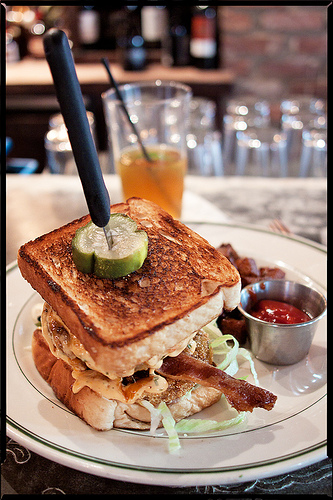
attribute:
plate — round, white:
[6, 217, 327, 487]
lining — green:
[3, 219, 332, 476]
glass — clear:
[101, 80, 193, 223]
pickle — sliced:
[71, 213, 148, 280]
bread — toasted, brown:
[17, 196, 222, 432]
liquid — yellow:
[119, 145, 187, 222]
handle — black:
[42, 28, 112, 227]